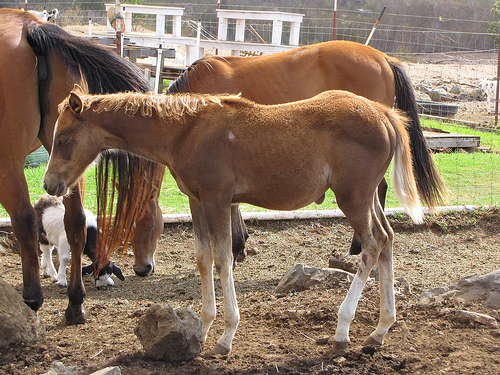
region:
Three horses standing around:
[0, 7, 446, 358]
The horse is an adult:
[0, 8, 164, 325]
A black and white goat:
[32, 195, 124, 291]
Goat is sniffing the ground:
[80, 259, 126, 291]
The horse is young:
[43, 84, 422, 353]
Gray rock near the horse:
[135, 302, 202, 362]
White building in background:
[89, 3, 302, 70]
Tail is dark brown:
[392, 59, 444, 216]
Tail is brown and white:
[391, 105, 423, 225]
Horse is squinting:
[56, 136, 71, 148]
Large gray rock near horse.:
[122, 291, 207, 368]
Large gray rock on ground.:
[440, 265, 497, 317]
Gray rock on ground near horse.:
[2, 293, 67, 374]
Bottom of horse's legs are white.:
[198, 279, 417, 351]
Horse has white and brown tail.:
[387, 111, 422, 227]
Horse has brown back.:
[227, 113, 399, 158]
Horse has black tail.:
[395, 70, 440, 187]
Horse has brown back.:
[233, 55, 367, 80]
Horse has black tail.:
[44, 33, 161, 87]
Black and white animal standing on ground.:
[35, 204, 135, 314]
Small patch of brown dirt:
[274, 309, 292, 330]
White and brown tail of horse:
[390, 125, 420, 210]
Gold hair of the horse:
[113, 96, 180, 108]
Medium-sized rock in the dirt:
[139, 306, 203, 356]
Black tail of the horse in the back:
[398, 75, 418, 102]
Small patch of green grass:
[461, 163, 474, 179]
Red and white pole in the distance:
[327, 3, 344, 29]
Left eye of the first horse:
[54, 137, 71, 148]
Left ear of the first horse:
[69, 95, 87, 115]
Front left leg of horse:
[218, 290, 241, 353]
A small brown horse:
[41, 89, 421, 356]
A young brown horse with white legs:
[45, 92, 419, 357]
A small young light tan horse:
[42, 91, 421, 356]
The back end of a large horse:
[0, 10, 157, 318]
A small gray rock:
[133, 307, 204, 358]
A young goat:
[30, 200, 121, 287]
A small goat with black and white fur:
[30, 201, 122, 287]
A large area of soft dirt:
[0, 207, 497, 370]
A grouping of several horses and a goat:
[2, 8, 447, 355]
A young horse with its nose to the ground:
[129, 39, 445, 275]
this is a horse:
[45, 89, 410, 335]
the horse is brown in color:
[225, 124, 305, 171]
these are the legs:
[321, 214, 398, 354]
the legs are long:
[326, 190, 397, 356]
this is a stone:
[141, 303, 206, 360]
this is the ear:
[68, 90, 83, 110]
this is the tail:
[395, 73, 419, 103]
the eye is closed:
[55, 129, 70, 148]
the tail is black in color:
[73, 36, 99, 58]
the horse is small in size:
[18, 84, 415, 284]